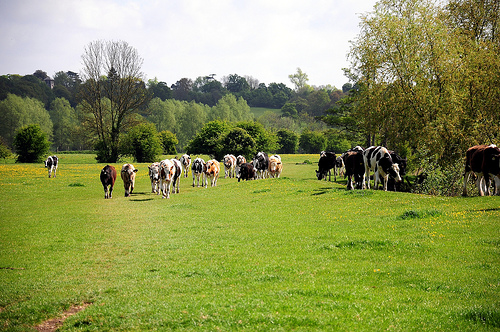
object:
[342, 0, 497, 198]
tree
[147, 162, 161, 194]
cow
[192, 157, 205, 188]
cows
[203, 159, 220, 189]
cow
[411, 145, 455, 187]
ground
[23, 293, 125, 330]
dirt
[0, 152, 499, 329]
grass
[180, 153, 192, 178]
cows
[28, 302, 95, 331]
bare patch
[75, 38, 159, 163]
tree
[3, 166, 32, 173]
flowers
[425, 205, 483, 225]
flowers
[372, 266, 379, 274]
flowers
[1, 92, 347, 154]
bushes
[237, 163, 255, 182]
cows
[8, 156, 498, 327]
field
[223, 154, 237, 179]
cow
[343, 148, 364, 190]
cow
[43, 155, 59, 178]
cow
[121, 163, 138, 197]
cow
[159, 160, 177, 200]
cow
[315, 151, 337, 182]
cow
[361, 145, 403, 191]
cow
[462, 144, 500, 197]
cow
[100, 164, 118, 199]
cow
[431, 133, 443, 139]
leaves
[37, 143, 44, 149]
leaves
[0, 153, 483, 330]
pasture